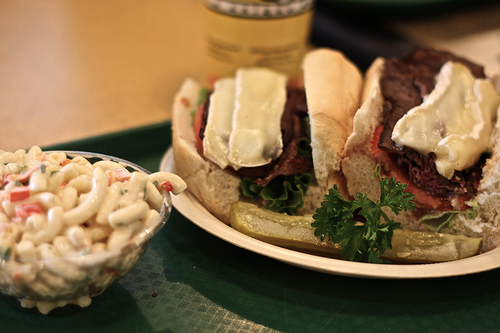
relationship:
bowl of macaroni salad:
[0, 146, 175, 316] [2, 144, 190, 316]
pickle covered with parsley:
[228, 196, 486, 267] [308, 162, 418, 267]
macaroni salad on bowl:
[2, 144, 190, 316] [0, 146, 175, 316]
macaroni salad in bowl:
[2, 144, 190, 316] [0, 146, 175, 316]